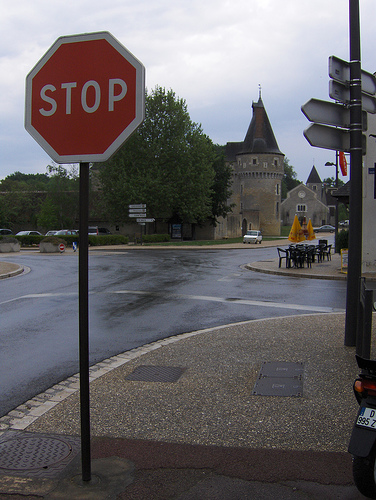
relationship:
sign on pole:
[24, 31, 145, 164] [80, 161, 92, 479]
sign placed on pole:
[24, 31, 145, 164] [80, 161, 92, 479]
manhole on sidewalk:
[0, 437, 71, 475] [0, 310, 365, 499]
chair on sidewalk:
[276, 244, 291, 267] [245, 252, 350, 281]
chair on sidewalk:
[319, 238, 329, 248] [245, 252, 350, 281]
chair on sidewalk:
[324, 244, 333, 259] [245, 252, 350, 281]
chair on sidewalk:
[292, 248, 305, 269] [245, 252, 350, 281]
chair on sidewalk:
[321, 244, 334, 261] [0, 310, 365, 499]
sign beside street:
[24, 31, 145, 164] [2, 235, 375, 431]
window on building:
[251, 157, 257, 166] [216, 90, 285, 241]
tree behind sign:
[97, 88, 215, 227] [24, 31, 145, 164]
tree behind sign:
[210, 152, 234, 226] [24, 31, 145, 164]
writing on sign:
[36, 79, 127, 120] [24, 31, 145, 164]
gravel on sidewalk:
[28, 313, 360, 451] [0, 310, 365, 499]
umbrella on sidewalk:
[286, 213, 307, 245] [245, 252, 350, 281]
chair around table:
[292, 248, 305, 269] [291, 247, 310, 254]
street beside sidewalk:
[2, 235, 375, 431] [0, 310, 365, 499]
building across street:
[216, 90, 285, 241] [2, 235, 375, 431]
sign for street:
[24, 31, 145, 164] [2, 235, 375, 431]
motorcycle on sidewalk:
[346, 356, 376, 500] [0, 310, 365, 499]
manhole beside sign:
[0, 437, 71, 475] [24, 31, 145, 164]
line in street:
[120, 288, 350, 315] [2, 235, 375, 431]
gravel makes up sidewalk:
[28, 313, 360, 451] [0, 310, 365, 499]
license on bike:
[354, 405, 375, 430] [346, 356, 376, 500]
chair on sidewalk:
[292, 248, 305, 269] [0, 310, 365, 499]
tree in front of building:
[210, 152, 234, 226] [216, 90, 285, 241]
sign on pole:
[327, 54, 375, 93] [344, 2, 363, 347]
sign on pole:
[330, 79, 375, 113] [344, 2, 363, 347]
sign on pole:
[300, 99, 368, 129] [344, 2, 363, 347]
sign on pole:
[303, 123, 367, 154] [344, 2, 363, 347]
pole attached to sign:
[80, 161, 92, 479] [24, 31, 145, 164]